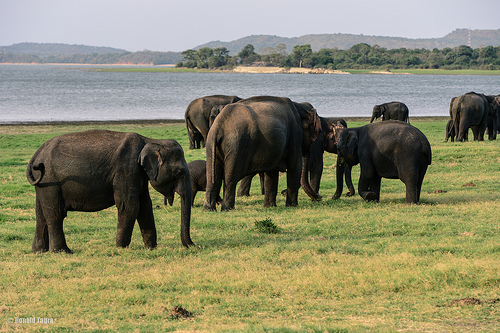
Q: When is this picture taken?
A: Daytime.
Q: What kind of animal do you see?
A: Elephants.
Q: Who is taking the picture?
A: A photographer.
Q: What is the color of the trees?
A: Green.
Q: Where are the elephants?
A: On the grass.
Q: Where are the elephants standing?
A: By a lake.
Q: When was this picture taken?
A: Daytime.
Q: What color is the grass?
A: Green.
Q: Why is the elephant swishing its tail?
A: To keep away flies.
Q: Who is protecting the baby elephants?
A: Their mothers.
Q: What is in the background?
A: Mountains.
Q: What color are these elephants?
A: Gray.